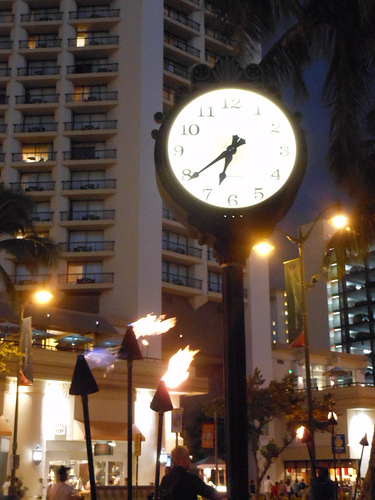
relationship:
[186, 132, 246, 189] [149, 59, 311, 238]
hands are on clock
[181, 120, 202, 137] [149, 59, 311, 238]
number on clock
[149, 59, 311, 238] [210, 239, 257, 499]
clock on a pole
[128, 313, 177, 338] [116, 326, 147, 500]
flame coming out of torch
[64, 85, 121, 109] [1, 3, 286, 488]
balcony on side of building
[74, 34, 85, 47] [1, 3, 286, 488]
light on building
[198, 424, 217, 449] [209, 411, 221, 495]
banner on a pole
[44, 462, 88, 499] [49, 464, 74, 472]
woman wearing a hat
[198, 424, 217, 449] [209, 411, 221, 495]
banner attached to a pole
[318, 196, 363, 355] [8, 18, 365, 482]
street light at night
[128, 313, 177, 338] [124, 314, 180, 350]
flame in a gust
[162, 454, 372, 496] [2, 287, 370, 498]
crowd at shopping center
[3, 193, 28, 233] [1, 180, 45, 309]
branches on tree